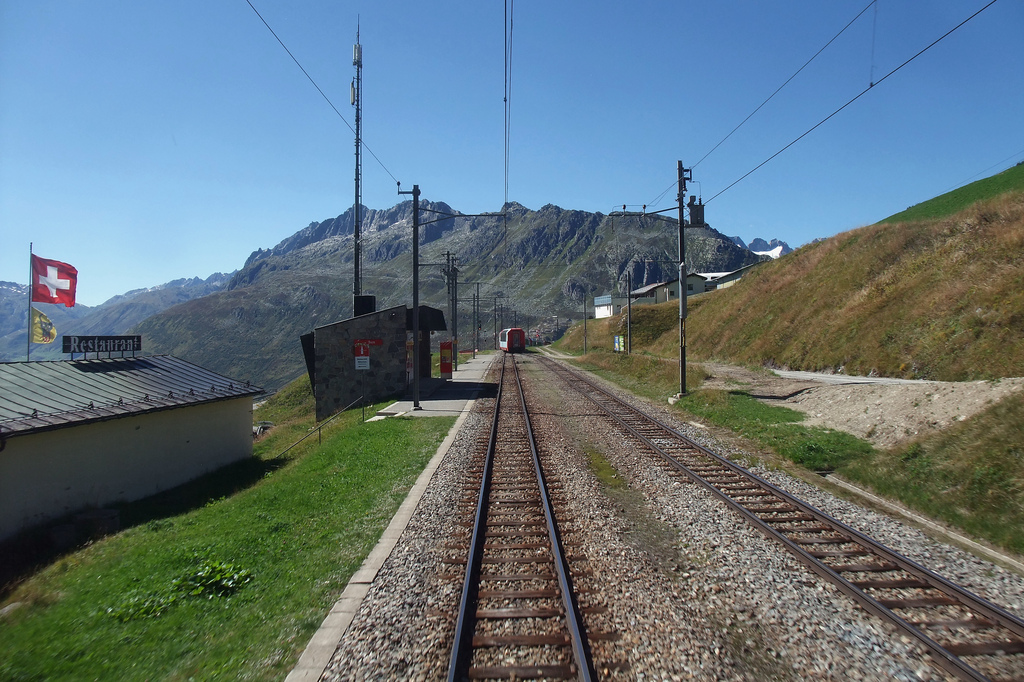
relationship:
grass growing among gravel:
[582, 445, 646, 512] [608, 443, 910, 679]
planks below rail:
[476, 582, 559, 650] [457, 348, 598, 678]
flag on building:
[13, 243, 77, 367] [2, 351, 266, 547]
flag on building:
[27, 241, 79, 361] [2, 351, 266, 547]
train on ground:
[498, 328, 526, 352] [0, 171, 1022, 679]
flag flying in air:
[27, 241, 79, 361] [4, 2, 1020, 309]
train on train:
[482, 322, 534, 361] [498, 328, 526, 352]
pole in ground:
[662, 158, 701, 406] [384, 306, 502, 431]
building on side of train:
[2, 344, 281, 542] [498, 328, 526, 352]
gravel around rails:
[551, 443, 745, 677] [441, 347, 1017, 680]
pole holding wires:
[668, 159, 688, 405] [636, 5, 1004, 202]